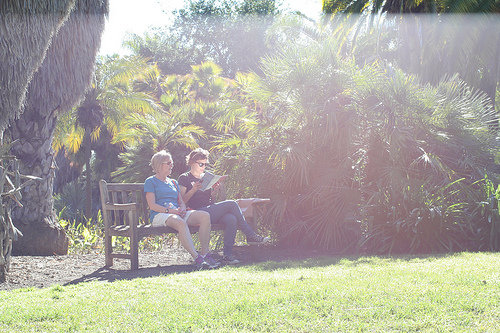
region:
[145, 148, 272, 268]
Two women sitting on a bench.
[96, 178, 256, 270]
A wooden bench two women are on.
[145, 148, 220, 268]
A short blonde haired woman with a blue shirt on sitting on a bench.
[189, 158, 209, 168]
Black sunglasses on a brown haired woman.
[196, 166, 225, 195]
A book a woman is holding.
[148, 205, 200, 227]
White shorts on a blonde woman.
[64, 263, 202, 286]
Black shadow of the bench.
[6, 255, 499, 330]
Bright green grass that the sun shines on in front of the women.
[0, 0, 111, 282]
Two very large furry trees behind the women.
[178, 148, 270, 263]
A woman in black glasses with short brown hair.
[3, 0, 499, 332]
sun glares on photograph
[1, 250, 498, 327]
bright sun shines on grass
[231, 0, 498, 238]
dense growing palms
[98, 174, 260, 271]
a wooden bench with arms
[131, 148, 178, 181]
a woman with blond hair and white framed glasses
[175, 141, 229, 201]
a lady with sunglasses reads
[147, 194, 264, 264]
white shorts and blue jeans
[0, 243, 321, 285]
a dirt and gravel path to bench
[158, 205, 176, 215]
wrist watch on right arm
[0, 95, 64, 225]
rough layered bark on tree trunk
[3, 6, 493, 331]
The sun is shining.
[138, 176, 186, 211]
She is wearing a blue shirt.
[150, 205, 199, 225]
She is wearing white pants.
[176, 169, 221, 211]
She is wearing a black shirt.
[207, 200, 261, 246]
She is wearing jeans.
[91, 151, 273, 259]
Two women sitting on a bench.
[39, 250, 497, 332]
The grass is green.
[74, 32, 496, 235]
The trees are leafy.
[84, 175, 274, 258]
The bench is brown.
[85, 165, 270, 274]
The bench is wooden.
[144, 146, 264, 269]
Two women sitting outside.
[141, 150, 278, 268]
Two people talking on bench.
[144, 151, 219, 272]
Woman in blue shirt and white shorts.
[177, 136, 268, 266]
Woman in black shirt and blue pants.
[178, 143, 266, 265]
Woman reading on bench.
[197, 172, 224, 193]
Book being read by a woman.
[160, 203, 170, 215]
Black watch being worn by a woman.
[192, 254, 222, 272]
Purple sneakers worn by a woman.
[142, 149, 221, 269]
Blonde woman sitting on bench.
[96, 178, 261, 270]
Wooden bench on a path.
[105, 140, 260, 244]
two women sitting on a bench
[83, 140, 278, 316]
two women sitting on a bench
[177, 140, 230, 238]
the woman is reading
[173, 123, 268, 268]
the woman is reading